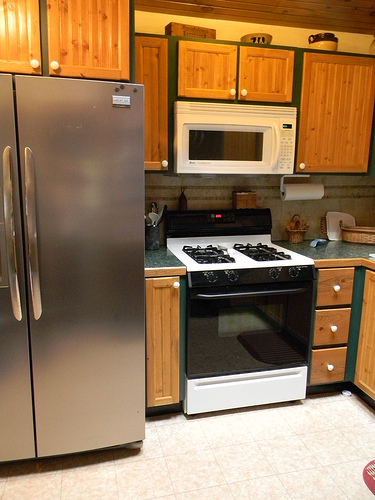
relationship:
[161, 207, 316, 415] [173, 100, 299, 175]
oven under microwave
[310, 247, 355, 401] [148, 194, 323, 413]
drawers next to stove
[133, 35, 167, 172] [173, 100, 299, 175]
cabinet on side of microwave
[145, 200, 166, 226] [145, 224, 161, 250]
utensils in container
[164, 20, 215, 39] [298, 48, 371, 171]
box above cabinet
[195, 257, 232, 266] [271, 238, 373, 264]
burner surrounding counter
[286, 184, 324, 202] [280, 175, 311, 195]
towels hanging from dispenser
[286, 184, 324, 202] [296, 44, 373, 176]
towels under cabinet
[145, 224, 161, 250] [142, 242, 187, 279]
container on counter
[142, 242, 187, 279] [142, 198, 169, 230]
counter holding utensils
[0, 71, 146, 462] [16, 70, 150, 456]
fridge with door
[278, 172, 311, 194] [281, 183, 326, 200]
dispenser with towels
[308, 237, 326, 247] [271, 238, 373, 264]
holder on counter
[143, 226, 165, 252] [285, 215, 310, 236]
container of utensils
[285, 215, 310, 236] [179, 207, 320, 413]
utensils to left of stove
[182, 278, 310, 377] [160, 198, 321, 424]
door of oven